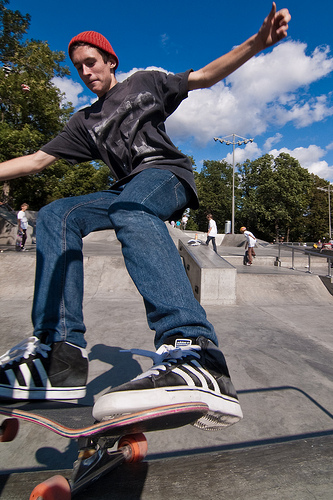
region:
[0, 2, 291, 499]
A man on a skateboard.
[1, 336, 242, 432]
A pair of shoes.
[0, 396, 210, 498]
A skateboard with wheels.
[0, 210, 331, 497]
People in a skate park.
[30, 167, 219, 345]
A pair of jeans.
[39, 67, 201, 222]
A tshirt on a kid.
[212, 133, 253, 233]
A pole with lights.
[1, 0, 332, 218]
A cloudy blue sky.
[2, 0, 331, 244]
Trees at a skate park.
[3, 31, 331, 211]
Clouds in the sky.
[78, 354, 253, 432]
black and white shoe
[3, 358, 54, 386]
three white stripes on the side of the shoe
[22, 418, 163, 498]
orange wheels on the bottom of the board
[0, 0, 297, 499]
man on a skateboard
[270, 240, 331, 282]
railing along the incline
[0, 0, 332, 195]
bright white clouds in the sky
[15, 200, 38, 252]
person standing with a skateboard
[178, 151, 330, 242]
dark green leaves on the trees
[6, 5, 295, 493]
A young man skateboarding.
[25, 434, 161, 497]
Wheels on skateboard are orange.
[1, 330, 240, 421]
A pair of black and white tennis shoes.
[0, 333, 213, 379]
White laces in tennis shoes.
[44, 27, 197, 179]
Young man wearing tee shirt.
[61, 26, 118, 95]
Young man wearing red hat.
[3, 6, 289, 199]
Skateboarder has arms out for balance.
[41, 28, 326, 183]
Large white clouds in sky.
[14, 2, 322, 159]
Sky is clear and blue.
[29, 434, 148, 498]
two wheels under the skateboard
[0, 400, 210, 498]
a skateboard with orange wheels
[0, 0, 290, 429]
young men at the skatepark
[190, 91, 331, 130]
white clouds in the blue sky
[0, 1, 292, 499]
a young man on a skateboard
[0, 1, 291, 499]
a teenage boy skateboarding in a park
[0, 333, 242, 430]
a pair of black and white sneakers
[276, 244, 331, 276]
a metal rail on poles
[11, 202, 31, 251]
a boy in the skatepark holding a skateboard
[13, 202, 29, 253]
a young boy in a white t-shirt holding a skateboard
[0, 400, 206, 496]
skateboard rolling in motion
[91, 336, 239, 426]
black and white sneakers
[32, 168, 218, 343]
boys blue denim jeans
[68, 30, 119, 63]
short red beanie hat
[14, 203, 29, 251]
boy standing with skateboard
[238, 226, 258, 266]
boy with helmet skateboarding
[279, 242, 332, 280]
grind rail for skateboarders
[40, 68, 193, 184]
black and gray t-shirt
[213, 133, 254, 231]
tall light post in park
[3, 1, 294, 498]
boy skater doing a trick